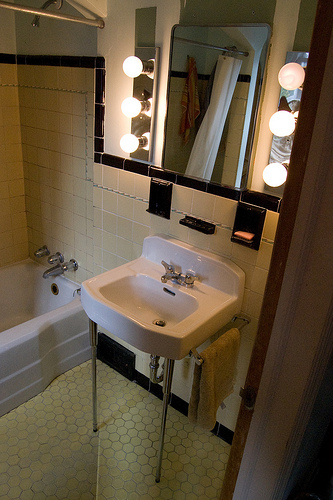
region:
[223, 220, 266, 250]
A BAR OF SOAP ON A HOLDER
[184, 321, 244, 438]
A TOWEL ON THE SIDE OF THE SINK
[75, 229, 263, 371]
A WHITE BATHROOM SINK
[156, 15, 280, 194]
A MIRROR OVER THE SINK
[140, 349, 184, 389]
PIPES UNDER THE SINK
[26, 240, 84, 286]
A BATHTUB FAUCET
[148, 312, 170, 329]
A BATHROOM SINK DRAIN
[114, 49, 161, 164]
A BATHROOM LIGHTING FIXTURE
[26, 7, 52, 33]
A METAL SHOWER HEAD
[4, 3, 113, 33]
A SHOWER CURTAIN ROD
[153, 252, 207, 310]
FAUCET IS SILVER STEEL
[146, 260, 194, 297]
FAUCET IS SILVER STEEL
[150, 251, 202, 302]
FAUCET IS SILVER STEEL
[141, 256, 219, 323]
FAUCET IS SILVER STEEL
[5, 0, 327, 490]
tile bathroom with dressing room lights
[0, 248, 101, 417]
white bathtub in bathroom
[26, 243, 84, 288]
silver bathtub water faucet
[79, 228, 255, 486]
stand-alone bathroom sink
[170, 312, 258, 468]
yellow hanging bathroom towel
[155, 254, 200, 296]
silver bathroom sink water faucet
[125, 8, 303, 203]
bathroom mirror with dressing room lights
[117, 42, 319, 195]
dressing room lights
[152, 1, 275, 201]
bathroom mirror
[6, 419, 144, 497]
hexagonal bathroom floor tiles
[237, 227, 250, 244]
A bar of pink soap.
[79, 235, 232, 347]
A porcelain sink.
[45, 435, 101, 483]
Yellow tiles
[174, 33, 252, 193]
A mirror reflecting the shower curtain.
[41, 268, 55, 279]
A silver-colored bathtub spout.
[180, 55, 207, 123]
A orange and yellow towel handing in the bathtub.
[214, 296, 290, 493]
Bathroom door is made of wood.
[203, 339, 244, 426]
a brown towel hanging from the sink.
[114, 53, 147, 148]
Bright lights attached to the wall.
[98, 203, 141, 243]
Yellow tiles on the wall.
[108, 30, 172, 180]
The lights are on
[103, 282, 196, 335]
The sink is white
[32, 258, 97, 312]
The tub is off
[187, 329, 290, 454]
There is a towel next to the sink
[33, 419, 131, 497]
The floor is yellowish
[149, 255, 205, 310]
The knobs are white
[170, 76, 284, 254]
There is a mirror above the sink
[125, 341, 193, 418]
Under the sink is metal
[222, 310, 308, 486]
The door is open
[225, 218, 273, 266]
There is soap above the sink